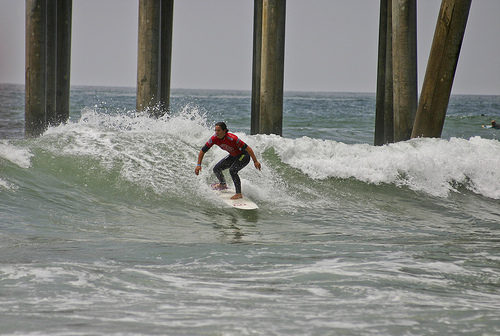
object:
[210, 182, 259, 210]
surfboard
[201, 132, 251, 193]
wetsuit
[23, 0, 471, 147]
pier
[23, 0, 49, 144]
pole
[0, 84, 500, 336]
water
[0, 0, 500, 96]
sky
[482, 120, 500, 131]
surfer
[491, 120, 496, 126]
head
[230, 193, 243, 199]
foot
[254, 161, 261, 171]
hand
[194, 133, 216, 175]
arm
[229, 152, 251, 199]
leg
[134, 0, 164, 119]
support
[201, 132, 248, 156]
shirt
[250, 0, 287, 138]
pillar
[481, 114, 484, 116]
swimmer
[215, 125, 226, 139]
face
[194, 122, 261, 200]
surfer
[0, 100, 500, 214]
waves